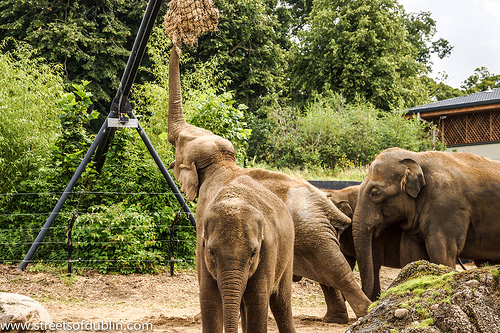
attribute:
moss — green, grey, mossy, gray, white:
[357, 257, 494, 329]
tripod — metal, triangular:
[11, 1, 191, 273]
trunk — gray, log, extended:
[158, 41, 193, 124]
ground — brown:
[0, 268, 200, 326]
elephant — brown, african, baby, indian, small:
[189, 170, 304, 332]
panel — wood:
[406, 105, 500, 148]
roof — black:
[398, 86, 500, 118]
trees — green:
[6, 3, 438, 159]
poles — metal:
[63, 211, 80, 278]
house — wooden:
[397, 88, 500, 153]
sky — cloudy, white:
[407, 1, 498, 79]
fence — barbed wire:
[0, 181, 196, 271]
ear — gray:
[399, 150, 428, 200]